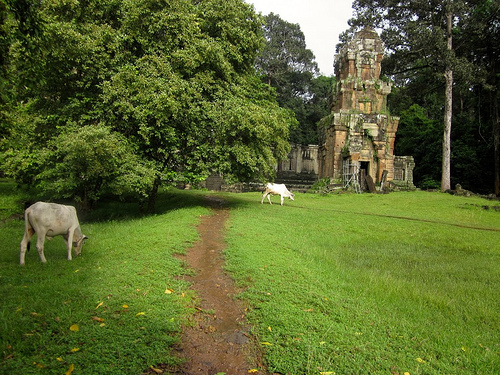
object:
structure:
[193, 20, 421, 197]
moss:
[362, 128, 380, 162]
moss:
[373, 79, 383, 95]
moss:
[318, 111, 352, 132]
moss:
[377, 105, 398, 126]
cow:
[16, 200, 89, 268]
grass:
[1, 179, 499, 374]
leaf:
[163, 285, 173, 295]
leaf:
[68, 322, 81, 333]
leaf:
[68, 345, 82, 354]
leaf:
[60, 360, 83, 374]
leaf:
[121, 302, 130, 310]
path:
[154, 191, 274, 374]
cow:
[259, 182, 296, 208]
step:
[287, 187, 322, 194]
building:
[276, 139, 321, 175]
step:
[282, 183, 317, 189]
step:
[273, 179, 316, 185]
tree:
[336, 0, 497, 198]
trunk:
[439, 9, 455, 197]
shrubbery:
[306, 176, 332, 195]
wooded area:
[292, 2, 499, 197]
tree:
[0, 0, 299, 214]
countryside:
[0, 1, 499, 375]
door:
[358, 159, 372, 193]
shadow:
[17, 187, 251, 227]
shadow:
[259, 199, 500, 233]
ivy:
[379, 96, 391, 127]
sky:
[235, 0, 499, 100]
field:
[2, 184, 500, 374]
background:
[186, 60, 499, 200]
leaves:
[464, 0, 498, 35]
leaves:
[458, 48, 496, 88]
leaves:
[385, 0, 409, 21]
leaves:
[410, 45, 438, 75]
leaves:
[470, 70, 498, 93]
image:
[0, 0, 500, 375]